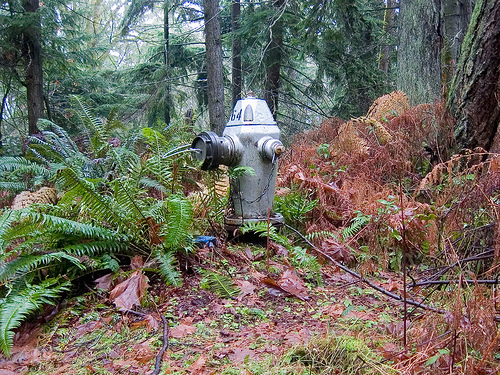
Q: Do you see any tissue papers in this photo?
A: No, there are no tissue papers.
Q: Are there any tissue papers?
A: No, there are no tissue papers.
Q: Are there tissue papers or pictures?
A: No, there are no tissue papers or pictures.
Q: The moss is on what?
A: The moss is on the trunk.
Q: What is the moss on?
A: The moss is on the trunk.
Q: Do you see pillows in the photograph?
A: No, there are no pillows.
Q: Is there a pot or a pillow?
A: No, there are no pillows or pots.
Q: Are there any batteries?
A: No, there are no batteries.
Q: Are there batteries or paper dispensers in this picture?
A: No, there are no batteries or paper dispensers.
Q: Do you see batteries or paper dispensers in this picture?
A: No, there are no batteries or paper dispensers.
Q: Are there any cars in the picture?
A: No, there are no cars.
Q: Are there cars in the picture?
A: No, there are no cars.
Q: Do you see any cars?
A: No, there are no cars.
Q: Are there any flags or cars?
A: No, there are no cars or flags.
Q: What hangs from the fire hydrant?
A: The chain hangs from the fire hydrant.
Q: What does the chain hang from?
A: The chain hangs from the hydrant.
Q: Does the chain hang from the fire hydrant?
A: Yes, the chain hangs from the fire hydrant.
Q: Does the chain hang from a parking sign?
A: No, the chain hangs from the fire hydrant.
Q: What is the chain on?
A: The chain is on the fire hydrant.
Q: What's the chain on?
A: The chain is on the fire hydrant.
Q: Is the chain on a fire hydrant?
A: Yes, the chain is on a fire hydrant.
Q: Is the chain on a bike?
A: No, the chain is on a fire hydrant.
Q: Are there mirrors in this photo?
A: No, there are no mirrors.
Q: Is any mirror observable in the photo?
A: No, there are no mirrors.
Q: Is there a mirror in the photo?
A: No, there are no mirrors.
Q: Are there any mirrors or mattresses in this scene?
A: No, there are no mirrors or mattresses.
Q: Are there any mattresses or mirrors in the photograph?
A: No, there are no mirrors or mattresses.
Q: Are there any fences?
A: No, there are no fences.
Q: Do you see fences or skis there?
A: No, there are no fences or skis.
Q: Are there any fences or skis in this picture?
A: No, there are no fences or skis.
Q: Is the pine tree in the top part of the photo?
A: Yes, the pine tree is in the top of the image.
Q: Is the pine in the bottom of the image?
A: No, the pine is in the top of the image.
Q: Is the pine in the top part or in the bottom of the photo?
A: The pine is in the top of the image.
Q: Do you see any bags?
A: No, there are no bags.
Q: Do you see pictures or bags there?
A: No, there are no bags or pictures.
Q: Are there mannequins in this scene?
A: No, there are no mannequins.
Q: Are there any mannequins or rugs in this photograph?
A: No, there are no mannequins or rugs.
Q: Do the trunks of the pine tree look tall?
A: Yes, the trunks are tall.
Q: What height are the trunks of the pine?
A: The trunks are tall.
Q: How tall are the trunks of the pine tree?
A: The trunks are tall.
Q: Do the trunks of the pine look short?
A: No, the trunks are tall.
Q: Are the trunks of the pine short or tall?
A: The trunks are tall.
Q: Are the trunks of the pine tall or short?
A: The trunks are tall.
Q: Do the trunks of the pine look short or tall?
A: The trunks are tall.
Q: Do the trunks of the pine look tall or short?
A: The trunks are tall.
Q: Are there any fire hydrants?
A: Yes, there is a fire hydrant.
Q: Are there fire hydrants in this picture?
A: Yes, there is a fire hydrant.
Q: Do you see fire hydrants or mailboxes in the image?
A: Yes, there is a fire hydrant.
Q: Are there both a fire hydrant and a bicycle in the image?
A: No, there is a fire hydrant but no bicycles.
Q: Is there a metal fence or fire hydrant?
A: Yes, there is a metal fire hydrant.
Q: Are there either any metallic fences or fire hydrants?
A: Yes, there is a metal fire hydrant.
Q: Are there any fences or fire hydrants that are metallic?
A: Yes, the fire hydrant is metallic.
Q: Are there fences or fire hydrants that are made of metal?
A: Yes, the fire hydrant is made of metal.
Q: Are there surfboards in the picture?
A: No, there are no surfboards.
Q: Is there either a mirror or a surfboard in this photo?
A: No, there are no surfboards or mirrors.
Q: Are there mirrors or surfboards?
A: No, there are no surfboards or mirrors.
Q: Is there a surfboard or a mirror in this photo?
A: No, there are no surfboards or mirrors.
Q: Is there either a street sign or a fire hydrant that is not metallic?
A: No, there is a fire hydrant but it is metallic.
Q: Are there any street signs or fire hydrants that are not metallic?
A: No, there is a fire hydrant but it is metallic.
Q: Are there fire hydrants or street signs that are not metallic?
A: No, there is a fire hydrant but it is metallic.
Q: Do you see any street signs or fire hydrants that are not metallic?
A: No, there is a fire hydrant but it is metallic.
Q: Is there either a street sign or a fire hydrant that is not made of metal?
A: No, there is a fire hydrant but it is made of metal.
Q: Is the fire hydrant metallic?
A: Yes, the fire hydrant is metallic.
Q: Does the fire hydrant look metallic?
A: Yes, the fire hydrant is metallic.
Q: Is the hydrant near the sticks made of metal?
A: Yes, the hydrant is made of metal.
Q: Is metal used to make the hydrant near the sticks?
A: Yes, the hydrant is made of metal.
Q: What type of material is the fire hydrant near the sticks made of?
A: The fire hydrant is made of metal.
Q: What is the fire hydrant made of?
A: The fire hydrant is made of metal.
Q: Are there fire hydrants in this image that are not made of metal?
A: No, there is a fire hydrant but it is made of metal.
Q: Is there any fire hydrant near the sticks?
A: Yes, there is a fire hydrant near the sticks.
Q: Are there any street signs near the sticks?
A: No, there is a fire hydrant near the sticks.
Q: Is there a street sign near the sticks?
A: No, there is a fire hydrant near the sticks.